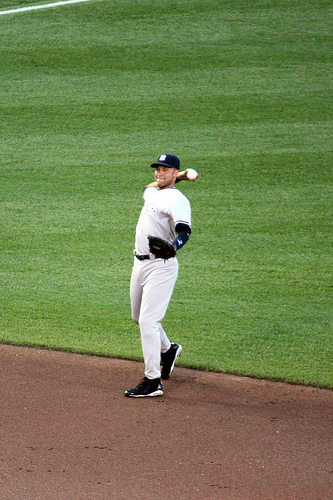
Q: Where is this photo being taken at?
A: Baseball field.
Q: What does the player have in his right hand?
A: A baseball.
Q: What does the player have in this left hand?
A: A baseball glove.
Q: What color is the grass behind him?
A: Green.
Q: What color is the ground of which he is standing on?
A: Brown.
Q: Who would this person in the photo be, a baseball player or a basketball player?
A: A baseball player.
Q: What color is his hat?
A: Dark blue.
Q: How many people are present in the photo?
A: One.